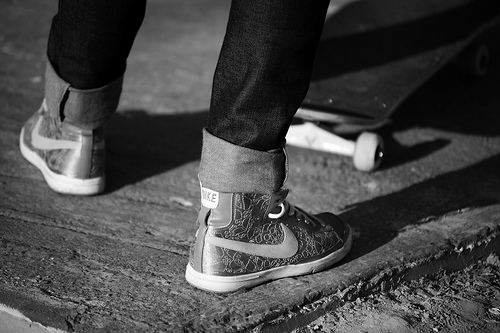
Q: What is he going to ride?
A: Skateboard.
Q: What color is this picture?
A: Black and white.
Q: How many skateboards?
A: 1.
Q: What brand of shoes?
A: Nike.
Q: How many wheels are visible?
A: 2.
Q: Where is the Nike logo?
A: On the side of the shoe.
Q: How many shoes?
A: 2.